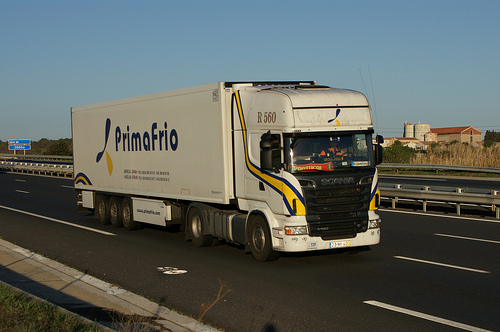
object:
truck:
[68, 77, 387, 262]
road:
[2, 172, 500, 330]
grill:
[301, 176, 369, 235]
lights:
[284, 225, 308, 235]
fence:
[1, 152, 498, 217]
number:
[262, 112, 279, 124]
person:
[321, 139, 347, 157]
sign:
[5, 136, 33, 151]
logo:
[88, 115, 190, 176]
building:
[401, 121, 487, 156]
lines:
[359, 249, 499, 331]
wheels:
[245, 209, 274, 264]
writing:
[113, 122, 181, 154]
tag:
[286, 162, 333, 174]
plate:
[328, 240, 351, 247]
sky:
[1, 2, 500, 79]